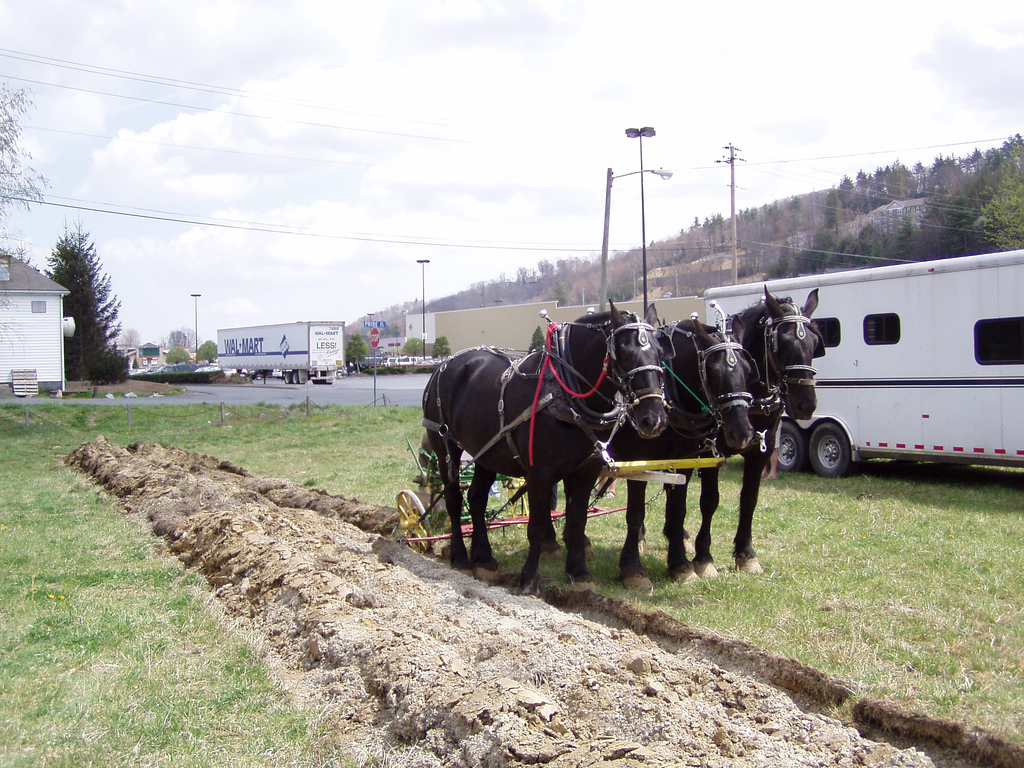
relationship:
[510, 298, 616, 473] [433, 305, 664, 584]
bridle on horse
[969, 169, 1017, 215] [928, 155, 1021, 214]
leaves on tree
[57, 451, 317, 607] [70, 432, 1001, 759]
plowed section of field